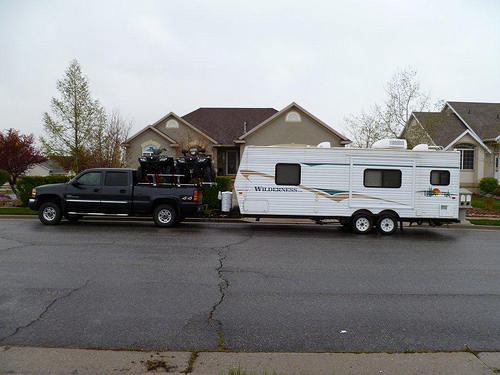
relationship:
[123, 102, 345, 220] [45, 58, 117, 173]
house near a tree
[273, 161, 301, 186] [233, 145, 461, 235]
window on camper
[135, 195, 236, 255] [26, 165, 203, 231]
back wheels on truck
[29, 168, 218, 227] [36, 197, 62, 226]
pickup truck has wheel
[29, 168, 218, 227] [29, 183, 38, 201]
pickup truck has headlight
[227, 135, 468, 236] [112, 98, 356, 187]
camper near house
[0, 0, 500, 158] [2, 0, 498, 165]
cloud on sky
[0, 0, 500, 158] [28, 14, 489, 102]
cloud in sky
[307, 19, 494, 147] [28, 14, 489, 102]
cloud in sky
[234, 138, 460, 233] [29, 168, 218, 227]
rv attached to pickup truck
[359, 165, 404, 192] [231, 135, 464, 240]
black window on rv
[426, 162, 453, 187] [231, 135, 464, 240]
black window on rv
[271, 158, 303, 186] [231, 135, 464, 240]
black window on rv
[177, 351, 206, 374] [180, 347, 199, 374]
grass growing in crack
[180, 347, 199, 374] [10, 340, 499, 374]
crack in sidewalk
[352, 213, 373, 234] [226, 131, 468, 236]
wheel on rv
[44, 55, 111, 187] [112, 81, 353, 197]
tree next to house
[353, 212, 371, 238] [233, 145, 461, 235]
wheel on a camper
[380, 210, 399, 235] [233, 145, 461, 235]
wheel on a camper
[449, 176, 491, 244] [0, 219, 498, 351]
mail box near a road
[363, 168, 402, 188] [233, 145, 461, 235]
black window on a camper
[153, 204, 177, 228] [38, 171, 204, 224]
back wheels on a truck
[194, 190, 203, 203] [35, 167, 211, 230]
light on a pickup truck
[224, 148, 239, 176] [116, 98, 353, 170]
door of a house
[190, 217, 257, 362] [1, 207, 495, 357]
crack in road